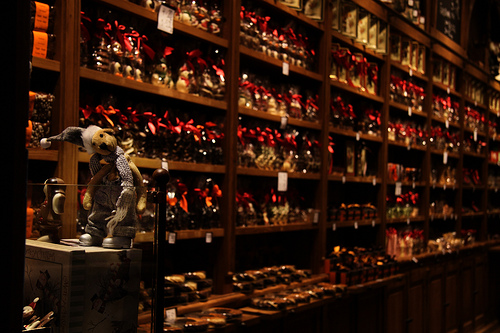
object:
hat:
[40, 125, 102, 154]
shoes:
[78, 233, 99, 246]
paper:
[157, 0, 174, 34]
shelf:
[239, 75, 318, 109]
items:
[212, 133, 218, 160]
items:
[208, 120, 235, 166]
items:
[174, 116, 198, 163]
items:
[157, 118, 165, 160]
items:
[125, 107, 138, 148]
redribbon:
[282, 132, 294, 144]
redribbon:
[256, 129, 271, 141]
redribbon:
[249, 83, 258, 94]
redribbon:
[212, 65, 224, 77]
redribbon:
[351, 105, 355, 117]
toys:
[393, 114, 437, 146]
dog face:
[94, 133, 117, 155]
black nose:
[99, 143, 108, 150]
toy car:
[247, 298, 284, 311]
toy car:
[163, 271, 213, 300]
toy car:
[310, 282, 336, 297]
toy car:
[229, 273, 255, 293]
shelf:
[225, 271, 326, 302]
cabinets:
[217, 242, 500, 332]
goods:
[202, 121, 430, 255]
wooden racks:
[248, 20, 432, 197]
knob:
[334, 287, 356, 305]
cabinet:
[338, 283, 415, 331]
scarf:
[89, 146, 135, 237]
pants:
[86, 183, 139, 239]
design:
[78, 261, 133, 315]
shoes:
[103, 235, 130, 249]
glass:
[25, 185, 142, 333]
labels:
[31, 0, 48, 59]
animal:
[39, 125, 147, 249]